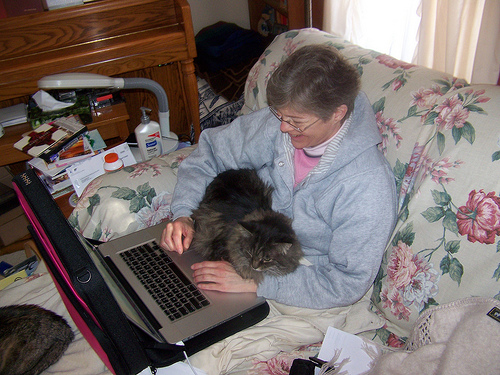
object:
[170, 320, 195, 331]
silver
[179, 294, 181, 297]
black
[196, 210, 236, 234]
long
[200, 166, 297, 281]
cat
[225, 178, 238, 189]
dark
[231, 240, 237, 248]
gray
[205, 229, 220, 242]
fluffy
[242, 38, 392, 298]
woman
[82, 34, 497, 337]
sofa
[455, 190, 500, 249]
flower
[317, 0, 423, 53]
window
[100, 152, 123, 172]
bottle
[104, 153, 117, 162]
red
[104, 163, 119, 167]
white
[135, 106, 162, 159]
bottle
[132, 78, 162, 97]
gray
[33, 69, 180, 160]
lamp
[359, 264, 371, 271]
gray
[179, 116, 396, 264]
shirt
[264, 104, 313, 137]
glasses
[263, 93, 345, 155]
face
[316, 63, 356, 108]
short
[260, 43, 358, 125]
hair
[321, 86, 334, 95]
gray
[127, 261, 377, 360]
lap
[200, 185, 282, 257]
hair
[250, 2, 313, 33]
cupboard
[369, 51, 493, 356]
cover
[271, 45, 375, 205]
elderly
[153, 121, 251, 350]
working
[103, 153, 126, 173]
tylenol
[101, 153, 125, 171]
one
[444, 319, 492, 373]
cream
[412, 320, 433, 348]
lace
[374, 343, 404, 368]
edge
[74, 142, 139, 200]
mail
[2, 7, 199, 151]
large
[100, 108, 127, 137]
wooden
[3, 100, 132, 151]
bench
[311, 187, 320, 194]
blue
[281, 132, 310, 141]
smile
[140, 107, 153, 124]
pump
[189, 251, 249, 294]
hands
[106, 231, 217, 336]
keyboard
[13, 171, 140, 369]
case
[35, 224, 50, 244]
pink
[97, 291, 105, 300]
black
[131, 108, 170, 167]
jar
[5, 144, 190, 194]
table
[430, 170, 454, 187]
flowers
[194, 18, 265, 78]
duffle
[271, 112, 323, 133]
silver